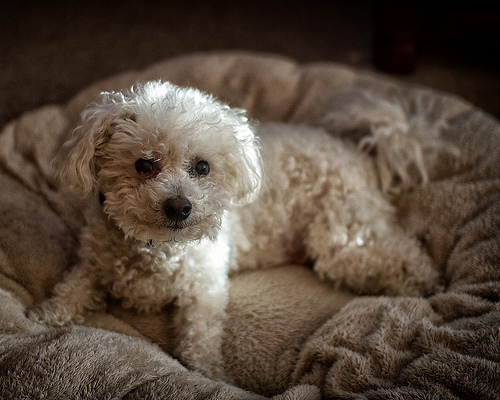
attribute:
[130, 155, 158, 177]
eye — dog's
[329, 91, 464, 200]
tail — white, fuzzy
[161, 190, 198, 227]
nose — small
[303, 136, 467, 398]
folds — big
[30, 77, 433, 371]
dog — fluffy, white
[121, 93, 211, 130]
fur — wavy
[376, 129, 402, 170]
ground — beige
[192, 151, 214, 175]
eye — black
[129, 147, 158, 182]
eye — black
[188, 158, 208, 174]
eye — black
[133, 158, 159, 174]
eye — black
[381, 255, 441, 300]
paw — dog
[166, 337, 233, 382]
paw — dog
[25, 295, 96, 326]
paw — dog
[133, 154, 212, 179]
eyes — round, black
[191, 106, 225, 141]
hair — white, wavy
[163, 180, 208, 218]
nose — black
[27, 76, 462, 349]
dog — white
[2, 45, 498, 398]
dog bed — beige, brown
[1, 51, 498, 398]
pillow — big, beige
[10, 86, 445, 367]
white puppy — little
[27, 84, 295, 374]
dog — white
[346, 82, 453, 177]
tail — strands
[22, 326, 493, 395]
surface — curved, smooth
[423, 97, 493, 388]
surface — curved, smooth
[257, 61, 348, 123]
surface — curved, smooth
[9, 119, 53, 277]
surface — curved, smooth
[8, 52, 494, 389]
bed — beige, dog, wrinkles, folds, edge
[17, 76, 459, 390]
dog — white, small, little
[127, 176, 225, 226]
mouth — of dog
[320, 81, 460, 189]
tail — fluffy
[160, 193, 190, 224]
nose — black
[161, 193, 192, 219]
nose — black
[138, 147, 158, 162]
fur — dog's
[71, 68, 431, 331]
hair — curly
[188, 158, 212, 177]
eye — dark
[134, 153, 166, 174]
eye — dark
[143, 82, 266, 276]
sun — reflective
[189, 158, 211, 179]
eye — brown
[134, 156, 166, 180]
eye — brown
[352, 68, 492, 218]
direction — every